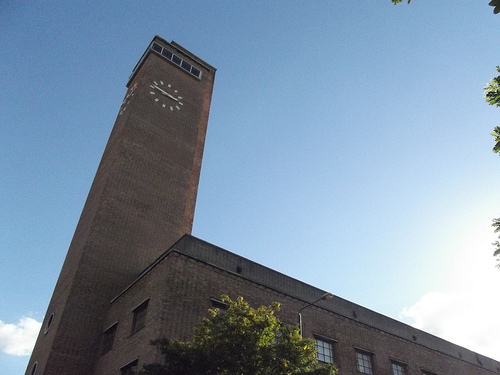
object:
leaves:
[120, 292, 338, 375]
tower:
[24, 32, 217, 373]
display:
[147, 78, 186, 114]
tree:
[140, 292, 340, 373]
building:
[100, 235, 500, 374]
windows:
[315, 335, 336, 364]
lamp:
[299, 292, 336, 315]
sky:
[0, 0, 499, 362]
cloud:
[0, 314, 42, 359]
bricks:
[249, 280, 260, 286]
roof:
[177, 232, 499, 370]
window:
[187, 66, 205, 81]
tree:
[485, 1, 499, 263]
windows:
[130, 299, 148, 334]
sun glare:
[411, 197, 500, 356]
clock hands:
[145, 80, 185, 112]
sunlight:
[416, 186, 499, 293]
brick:
[186, 255, 199, 262]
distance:
[22, 32, 500, 374]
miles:
[0, 1, 499, 374]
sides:
[30, 55, 148, 357]